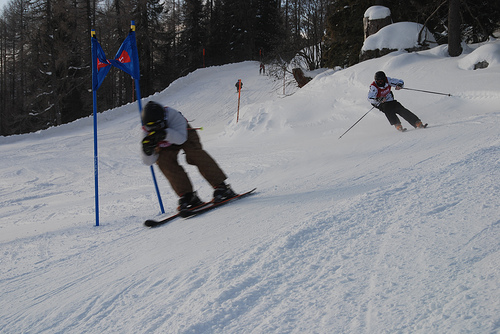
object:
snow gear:
[141, 129, 166, 156]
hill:
[0, 41, 500, 334]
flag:
[91, 20, 165, 226]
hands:
[141, 129, 167, 157]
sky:
[0, 0, 325, 61]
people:
[235, 63, 265, 93]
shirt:
[140, 106, 188, 166]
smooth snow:
[234, 22, 500, 158]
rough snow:
[0, 5, 500, 334]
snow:
[362, 21, 437, 51]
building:
[358, 5, 439, 62]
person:
[139, 100, 236, 211]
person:
[367, 71, 423, 130]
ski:
[145, 199, 215, 227]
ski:
[180, 188, 257, 218]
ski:
[400, 128, 407, 132]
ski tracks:
[0, 62, 500, 334]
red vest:
[369, 77, 391, 97]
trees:
[0, 0, 500, 137]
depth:
[359, 5, 438, 63]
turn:
[337, 70, 453, 139]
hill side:
[0, 42, 500, 334]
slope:
[0, 43, 500, 334]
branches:
[0, 0, 290, 136]